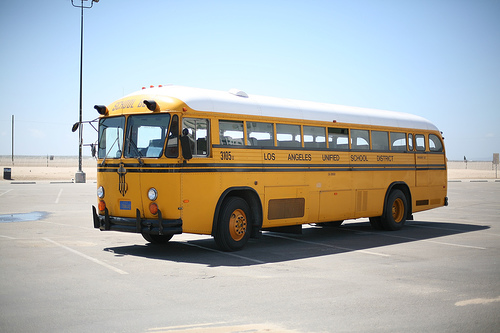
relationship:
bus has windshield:
[97, 87, 463, 240] [126, 117, 169, 153]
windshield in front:
[126, 117, 169, 153] [106, 111, 187, 153]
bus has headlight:
[97, 87, 463, 240] [146, 187, 160, 201]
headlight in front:
[146, 187, 160, 201] [106, 111, 187, 153]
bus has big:
[97, 87, 463, 240] [214, 196, 256, 252]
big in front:
[214, 196, 256, 252] [153, 182, 217, 256]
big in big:
[214, 196, 256, 252] [201, 193, 269, 274]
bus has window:
[97, 87, 463, 240] [212, 110, 253, 149]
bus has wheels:
[97, 87, 463, 240] [369, 184, 414, 235]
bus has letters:
[97, 87, 463, 240] [257, 144, 345, 167]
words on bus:
[261, 144, 401, 167] [97, 87, 463, 240]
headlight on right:
[146, 187, 160, 201] [90, 182, 113, 202]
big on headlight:
[214, 196, 256, 252] [146, 188, 159, 201]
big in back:
[214, 196, 256, 252] [369, 184, 414, 235]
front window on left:
[126, 117, 169, 153] [117, 114, 246, 209]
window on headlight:
[212, 110, 253, 149] [146, 188, 159, 201]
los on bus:
[253, 144, 286, 165] [97, 87, 463, 240]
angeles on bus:
[277, 148, 318, 169] [97, 87, 463, 240]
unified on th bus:
[318, 150, 347, 169] [97, 87, 463, 240]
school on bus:
[342, 149, 377, 169] [97, 87, 463, 240]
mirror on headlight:
[175, 120, 199, 170] [146, 188, 159, 201]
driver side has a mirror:
[131, 105, 205, 254] [175, 120, 199, 170]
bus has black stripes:
[97, 87, 463, 240] [197, 163, 449, 173]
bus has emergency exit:
[97, 87, 463, 240] [413, 125, 436, 195]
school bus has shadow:
[110, 102, 439, 158] [107, 232, 476, 257]